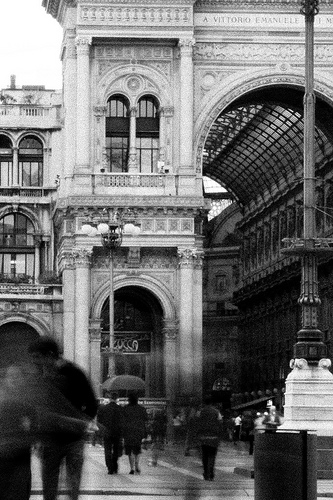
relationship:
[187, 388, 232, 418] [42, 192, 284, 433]
umbrella getting wet by rain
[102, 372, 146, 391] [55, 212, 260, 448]
umbrella getting wet by rain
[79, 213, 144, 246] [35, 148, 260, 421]
umbrella getting wet by rain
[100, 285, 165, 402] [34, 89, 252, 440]
arch on building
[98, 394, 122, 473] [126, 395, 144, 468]
man walking next to a woman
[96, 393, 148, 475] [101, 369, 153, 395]
people under an umbrella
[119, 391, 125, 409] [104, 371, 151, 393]
rod on umbrella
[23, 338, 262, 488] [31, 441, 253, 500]
people on ground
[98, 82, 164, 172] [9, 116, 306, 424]
two windows on side of building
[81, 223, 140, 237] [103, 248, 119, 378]
circle on top of a lamppost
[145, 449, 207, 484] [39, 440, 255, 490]
line on ground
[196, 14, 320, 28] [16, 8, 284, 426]
writing on top of building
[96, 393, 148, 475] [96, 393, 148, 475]
people are people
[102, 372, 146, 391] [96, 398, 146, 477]
umbrella over people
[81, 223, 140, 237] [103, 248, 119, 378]
circle on lamppost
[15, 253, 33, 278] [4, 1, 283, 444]
window of building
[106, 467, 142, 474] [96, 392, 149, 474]
feet of people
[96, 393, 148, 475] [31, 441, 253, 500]
people walking on a ground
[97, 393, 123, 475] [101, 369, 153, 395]
man under umbrella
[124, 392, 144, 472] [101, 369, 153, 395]
woman under umbrella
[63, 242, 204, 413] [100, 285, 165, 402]
columns of both sides of arch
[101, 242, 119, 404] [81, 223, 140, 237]
lamppost with circle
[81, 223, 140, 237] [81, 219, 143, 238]
circle in a circle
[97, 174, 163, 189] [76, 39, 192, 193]
railing between columns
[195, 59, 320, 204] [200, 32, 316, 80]
beams supporting roof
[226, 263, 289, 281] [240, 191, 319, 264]
border of medallions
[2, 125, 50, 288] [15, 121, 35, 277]
arches on different levels in a vertical line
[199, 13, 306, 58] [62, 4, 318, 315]
borders on building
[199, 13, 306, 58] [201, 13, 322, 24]
borders with writing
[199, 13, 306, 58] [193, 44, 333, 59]
borders with borders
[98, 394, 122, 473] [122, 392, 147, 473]
man and woman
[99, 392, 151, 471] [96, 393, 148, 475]
people walking people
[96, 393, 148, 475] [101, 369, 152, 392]
people standing under an umbrella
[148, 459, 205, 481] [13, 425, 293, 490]
line on ground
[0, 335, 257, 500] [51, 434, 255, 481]
people on walkway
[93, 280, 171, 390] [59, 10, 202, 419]
arch on building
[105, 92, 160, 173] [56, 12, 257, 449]
two windows on building